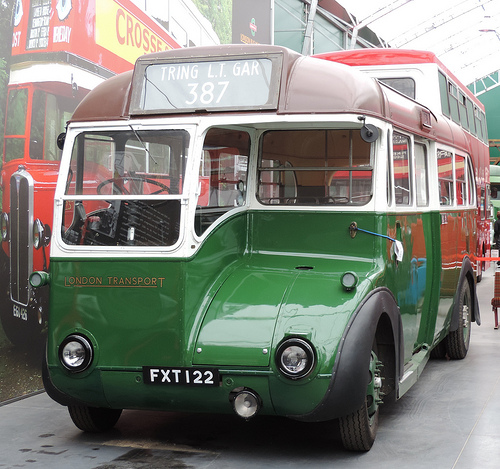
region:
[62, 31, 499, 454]
the bus is vintage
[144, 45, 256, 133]
bus number is 387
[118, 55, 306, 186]
bus number is 387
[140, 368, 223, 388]
Black licence plate with white letters.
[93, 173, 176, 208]
Black steering wheel inside of bus.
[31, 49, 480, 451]
Small green bus going down the street.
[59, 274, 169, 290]
'London Transport' written in gold.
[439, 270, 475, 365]
Back tire of bus.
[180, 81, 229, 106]
'387' written in white.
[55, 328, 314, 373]
Two matching front head lights.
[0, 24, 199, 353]
Picture of large red bus on billboard.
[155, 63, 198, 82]
'Tring' written in white.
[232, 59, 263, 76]
'Gar' written in white.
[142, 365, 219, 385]
the black license plate on the bus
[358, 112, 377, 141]
the mirror on the bus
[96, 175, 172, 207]
the steering wheel in the bus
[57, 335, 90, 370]
the light on the front of the bus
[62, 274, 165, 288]
the words on the front of the bus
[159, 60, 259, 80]
the lettering at the top of the bus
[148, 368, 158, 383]
the letter "F" on the license plate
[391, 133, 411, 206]
the window on the side of the bus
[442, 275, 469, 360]
the back tire on the bus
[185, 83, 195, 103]
the number 3 on the bus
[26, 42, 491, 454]
A green colored vehicle.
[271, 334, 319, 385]
A headlight on a vehicle.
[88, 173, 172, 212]
The steering wheel on a vehicle.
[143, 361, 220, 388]
A tag on the vehicle.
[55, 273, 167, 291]
A name on the vehicle.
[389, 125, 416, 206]
A window on a vehicle.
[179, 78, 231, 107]
Numbers on a vehicle.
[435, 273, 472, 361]
A tire on a vehicle.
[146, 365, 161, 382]
The letter F on a vehicle tag.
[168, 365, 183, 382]
The letter T on a vehicle tag.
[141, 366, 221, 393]
the license plate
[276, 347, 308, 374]
headlight on the bus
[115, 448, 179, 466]
spots on ground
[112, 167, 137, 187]
the steering wheel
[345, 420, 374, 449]
the front tire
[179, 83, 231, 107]
number on the bus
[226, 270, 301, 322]
the bus is green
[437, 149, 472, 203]
windows on the bus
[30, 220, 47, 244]
a mirror on the bus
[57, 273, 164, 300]
writing on the bus